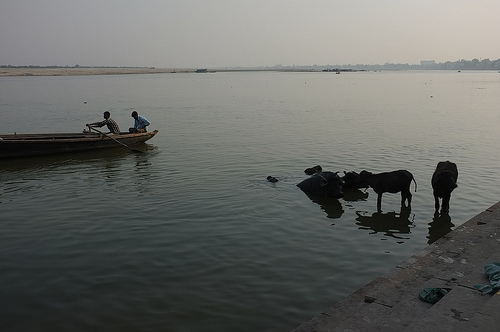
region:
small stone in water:
[260, 164, 287, 191]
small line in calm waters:
[116, 201, 276, 254]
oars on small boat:
[85, 124, 130, 159]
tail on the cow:
[403, 170, 422, 196]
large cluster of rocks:
[284, 156, 374, 216]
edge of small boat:
[145, 122, 160, 145]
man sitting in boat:
[124, 109, 162, 152]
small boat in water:
[20, 109, 227, 169]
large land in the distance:
[28, 59, 203, 89]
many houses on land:
[324, 47, 492, 77]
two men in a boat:
[73, 105, 158, 153]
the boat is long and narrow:
[2, 125, 158, 160]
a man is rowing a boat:
[80, 106, 130, 157]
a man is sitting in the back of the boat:
[123, 107, 158, 152]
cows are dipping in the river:
[263, 157, 458, 227]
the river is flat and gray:
[6, 68, 496, 326]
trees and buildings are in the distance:
[5, 55, 498, 86]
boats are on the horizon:
[332, 65, 463, 76]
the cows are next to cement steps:
[262, 156, 497, 327]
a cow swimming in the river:
[257, 167, 291, 188]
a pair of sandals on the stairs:
[416, 275, 455, 307]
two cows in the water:
[356, 153, 466, 235]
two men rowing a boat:
[1, 90, 177, 163]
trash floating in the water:
[259, 145, 354, 219]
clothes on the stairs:
[476, 249, 498, 308]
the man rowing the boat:
[70, 99, 120, 165]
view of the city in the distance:
[275, 53, 488, 113]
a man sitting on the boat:
[124, 97, 153, 139]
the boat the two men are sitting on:
[3, 127, 163, 161]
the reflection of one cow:
[354, 207, 419, 248]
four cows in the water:
[250, 156, 472, 222]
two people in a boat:
[81, 110, 160, 138]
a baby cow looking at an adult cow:
[352, 164, 419, 217]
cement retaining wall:
[284, 179, 498, 329]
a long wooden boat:
[0, 125, 162, 169]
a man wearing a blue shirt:
[120, 103, 157, 141]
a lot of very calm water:
[0, 69, 497, 325]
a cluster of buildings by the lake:
[416, 56, 498, 71]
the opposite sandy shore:
[0, 61, 211, 80]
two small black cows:
[353, 156, 478, 213]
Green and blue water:
[51, 167, 121, 191]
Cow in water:
[348, 156, 443, 231]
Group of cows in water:
[271, 109, 499, 235]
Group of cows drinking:
[251, 141, 499, 226]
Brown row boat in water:
[21, 121, 127, 158]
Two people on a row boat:
[76, 101, 193, 169]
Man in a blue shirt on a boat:
[130, 108, 167, 135]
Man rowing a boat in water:
[73, 111, 162, 168]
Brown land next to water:
[33, 58, 158, 91]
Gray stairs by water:
[373, 211, 489, 330]